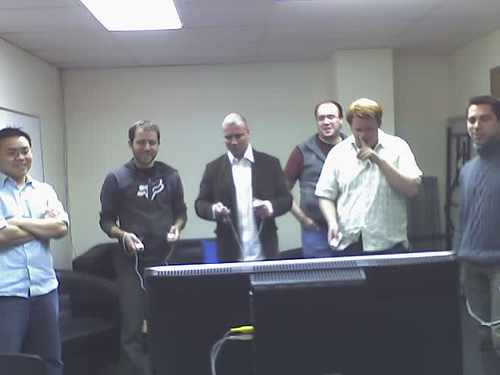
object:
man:
[314, 100, 421, 259]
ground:
[396, 235, 447, 252]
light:
[93, 2, 180, 32]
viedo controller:
[216, 199, 270, 250]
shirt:
[314, 138, 417, 251]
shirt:
[105, 165, 182, 252]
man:
[0, 122, 64, 371]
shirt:
[0, 171, 61, 297]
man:
[98, 121, 186, 373]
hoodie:
[98, 159, 188, 257]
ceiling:
[0, 0, 493, 56]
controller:
[136, 236, 182, 254]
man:
[460, 92, 499, 373]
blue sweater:
[457, 147, 499, 265]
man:
[192, 110, 293, 262]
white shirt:
[235, 159, 255, 263]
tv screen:
[142, 261, 455, 373]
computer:
[143, 257, 465, 368]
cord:
[211, 324, 257, 374]